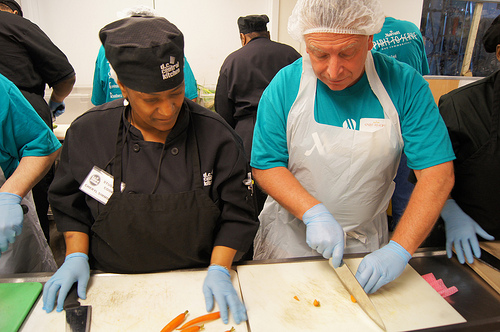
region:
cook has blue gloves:
[280, 200, 433, 301]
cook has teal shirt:
[265, 64, 440, 233]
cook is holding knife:
[305, 231, 390, 328]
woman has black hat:
[86, 10, 173, 110]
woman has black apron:
[76, 113, 250, 279]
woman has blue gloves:
[31, 267, 254, 320]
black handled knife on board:
[44, 281, 95, 322]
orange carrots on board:
[124, 307, 231, 327]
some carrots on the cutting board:
[160, 309, 222, 330]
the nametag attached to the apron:
[78, 162, 126, 205]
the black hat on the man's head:
[98, 18, 187, 88]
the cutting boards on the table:
[86, 245, 466, 330]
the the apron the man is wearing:
[252, 56, 398, 257]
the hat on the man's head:
[238, 14, 270, 34]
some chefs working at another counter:
[1, 0, 433, 127]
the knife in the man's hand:
[326, 252, 392, 329]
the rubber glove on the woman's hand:
[37, 250, 93, 312]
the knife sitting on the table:
[63, 283, 90, 329]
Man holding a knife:
[314, 234, 384, 330]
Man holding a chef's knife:
[328, 246, 390, 330]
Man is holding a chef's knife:
[325, 246, 392, 330]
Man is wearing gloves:
[297, 198, 410, 296]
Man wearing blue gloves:
[301, 198, 416, 297]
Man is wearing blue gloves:
[299, 198, 414, 295]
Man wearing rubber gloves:
[297, 197, 412, 296]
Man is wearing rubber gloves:
[298, 198, 416, 300]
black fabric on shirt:
[99, 105, 125, 133]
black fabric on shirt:
[58, 142, 90, 170]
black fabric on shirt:
[56, 187, 87, 218]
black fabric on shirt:
[124, 140, 154, 165]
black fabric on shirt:
[119, 169, 146, 196]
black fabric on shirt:
[161, 130, 196, 188]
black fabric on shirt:
[187, 105, 219, 148]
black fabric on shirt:
[219, 148, 246, 180]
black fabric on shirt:
[231, 182, 261, 214]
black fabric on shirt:
[215, 223, 246, 253]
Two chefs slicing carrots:
[55, 0, 462, 300]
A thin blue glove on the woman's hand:
[202, 262, 250, 317]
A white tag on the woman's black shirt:
[78, 165, 130, 207]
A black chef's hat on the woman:
[99, 13, 192, 88]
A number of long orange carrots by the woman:
[154, 298, 238, 330]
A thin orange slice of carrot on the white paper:
[311, 297, 327, 308]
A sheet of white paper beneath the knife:
[238, 262, 457, 329]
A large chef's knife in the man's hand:
[329, 253, 391, 330]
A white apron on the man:
[253, 54, 405, 261]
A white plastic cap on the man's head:
[287, 0, 390, 47]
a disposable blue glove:
[302, 203, 349, 260]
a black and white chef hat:
[100, 11, 182, 89]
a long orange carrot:
[180, 303, 220, 329]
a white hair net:
[280, 0, 391, 40]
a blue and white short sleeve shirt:
[250, 50, 460, 195]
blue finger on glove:
[75, 276, 88, 301]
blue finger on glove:
[56, 280, 71, 314]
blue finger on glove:
[47, 278, 58, 314]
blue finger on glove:
[41, 274, 51, 306]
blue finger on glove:
[203, 283, 216, 311]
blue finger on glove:
[214, 294, 229, 322]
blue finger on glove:
[225, 293, 243, 322]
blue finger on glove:
[443, 239, 453, 258]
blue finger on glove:
[453, 238, 467, 264]